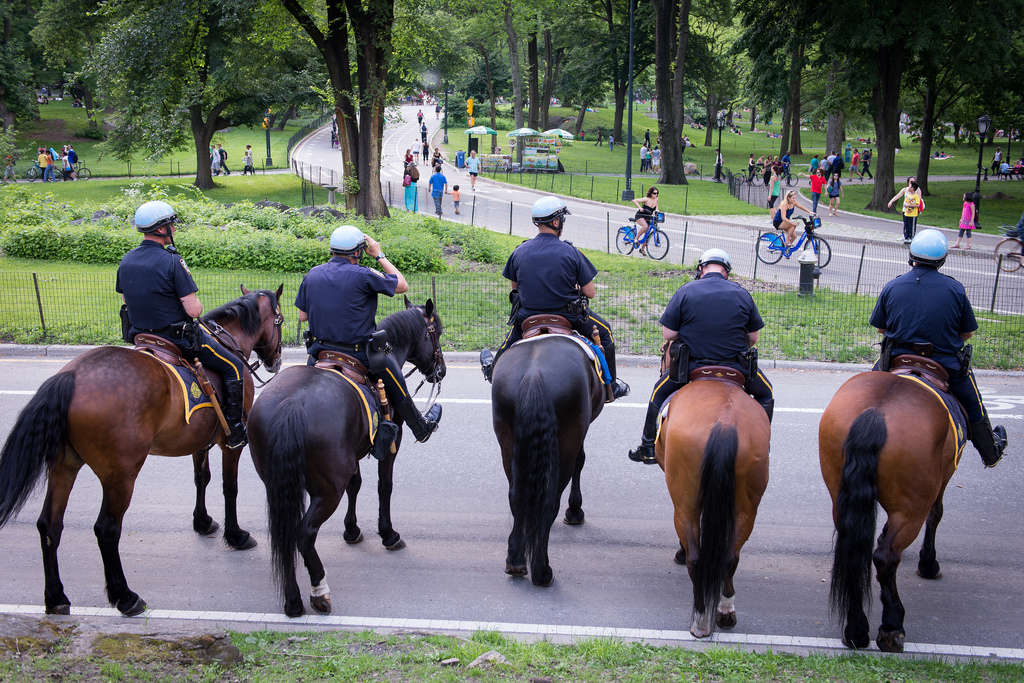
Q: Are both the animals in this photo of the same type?
A: Yes, all the animals are horses.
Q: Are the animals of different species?
A: No, all the animals are horses.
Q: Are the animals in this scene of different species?
A: No, all the animals are horses.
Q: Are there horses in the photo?
A: Yes, there is a horse.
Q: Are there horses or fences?
A: Yes, there is a horse.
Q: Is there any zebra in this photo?
A: No, there are no zebras.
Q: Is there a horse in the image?
A: Yes, there is a horse.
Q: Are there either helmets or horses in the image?
A: Yes, there is a horse.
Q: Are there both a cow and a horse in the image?
A: No, there is a horse but no cows.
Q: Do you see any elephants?
A: No, there are no elephants.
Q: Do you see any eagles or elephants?
A: No, there are no elephants or eagles.